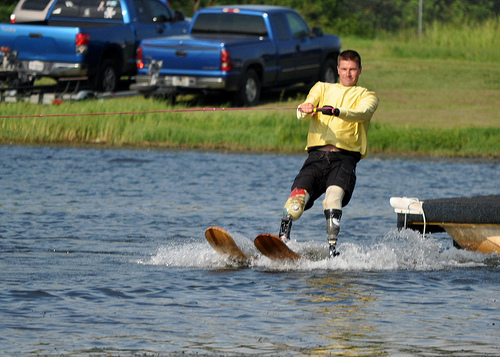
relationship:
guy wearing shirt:
[273, 43, 392, 258] [294, 72, 389, 162]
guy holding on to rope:
[277, 49, 381, 259] [0, 90, 340, 112]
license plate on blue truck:
[26, 56, 44, 73] [0, 0, 193, 93]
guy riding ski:
[277, 49, 381, 259] [253, 231, 300, 263]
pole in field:
[414, 6, 427, 51] [4, 32, 496, 157]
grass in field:
[376, 39, 488, 127] [4, 32, 496, 157]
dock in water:
[388, 196, 498, 254] [1, 138, 498, 355]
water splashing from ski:
[1, 138, 498, 355] [251, 233, 300, 264]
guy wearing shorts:
[277, 49, 381, 259] [288, 145, 359, 199]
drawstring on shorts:
[318, 147, 333, 165] [284, 139, 364, 213]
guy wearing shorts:
[277, 49, 381, 259] [288, 137, 369, 213]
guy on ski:
[277, 49, 381, 259] [203, 225, 248, 262]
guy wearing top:
[277, 49, 381, 259] [296, 82, 379, 157]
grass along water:
[1, 94, 498, 153] [6, 150, 478, 342]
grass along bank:
[1, 94, 498, 153] [7, 122, 462, 164]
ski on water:
[205, 224, 247, 264] [99, 175, 184, 213]